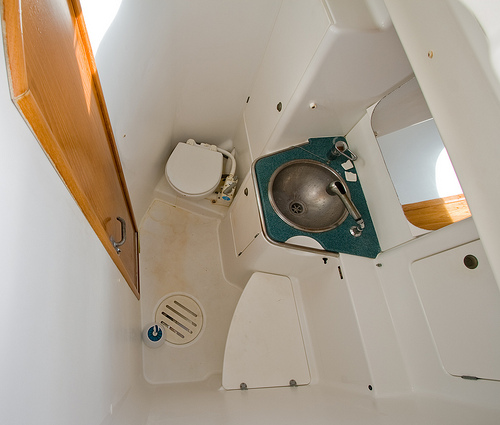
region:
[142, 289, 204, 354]
round white grate in floor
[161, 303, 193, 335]
lines in the grate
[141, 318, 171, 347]
blue plug on the floor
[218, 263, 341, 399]
white seat in the bathroo,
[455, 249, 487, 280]
round black handle on washer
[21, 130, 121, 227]
long brown wooden door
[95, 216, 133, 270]
silver handle on brown doo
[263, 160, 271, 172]
dark blue color on sink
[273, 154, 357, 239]
silver bowl in sink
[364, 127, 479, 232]
mirror on the wall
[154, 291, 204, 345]
Drain in bathroom floor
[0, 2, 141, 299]
Door to bathroom in camper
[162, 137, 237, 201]
Small toilet in camper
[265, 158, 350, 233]
Small round bathroom sink in camper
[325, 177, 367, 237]
Water nozzle in camper bathroom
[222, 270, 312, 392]
Foldable seat or shelf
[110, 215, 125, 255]
Door handle for camper bathroom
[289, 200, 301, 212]
Drain on bathroom sink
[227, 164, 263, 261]
Access door on camper bathroom sink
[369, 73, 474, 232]
Mirror in camper bathroom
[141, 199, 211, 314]
Yellow stain on the floor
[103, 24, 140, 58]
Part of white wall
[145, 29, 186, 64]
Snow covering the ground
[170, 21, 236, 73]
Snow covering the ground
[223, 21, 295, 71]
Snow covering the ground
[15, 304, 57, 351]
Snow covering the ground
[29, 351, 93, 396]
Snow covering the ground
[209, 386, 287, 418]
Snow covering the ground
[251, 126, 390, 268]
green and stainless steel sink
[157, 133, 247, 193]
top of the white toilet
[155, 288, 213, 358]
round drain in the floor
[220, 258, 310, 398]
corner seat to sit on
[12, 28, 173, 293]
brown wooden bathroom door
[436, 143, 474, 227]
sunlight shining into bathroom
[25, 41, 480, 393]
view from atop the bathroom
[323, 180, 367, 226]
stainless steel faucet in the bathroom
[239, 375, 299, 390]
two screws in the side of the seat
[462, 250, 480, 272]
hole in the bathroom sink cover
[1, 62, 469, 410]
lavatory in a ship or boat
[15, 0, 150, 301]
wooden bathroom door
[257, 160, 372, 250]
stainless steel sink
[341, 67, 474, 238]
mirror above the sink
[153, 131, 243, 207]
toilet in the bathroom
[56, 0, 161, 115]
light shining into the restroom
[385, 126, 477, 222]
a reflection of light shining in the mirror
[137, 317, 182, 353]
scrub brush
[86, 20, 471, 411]
lavatory restroom from a top view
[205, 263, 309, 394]
plastic seat